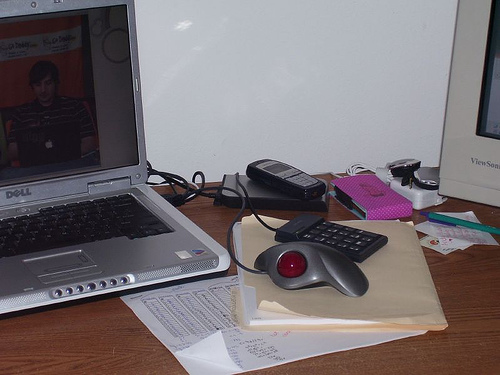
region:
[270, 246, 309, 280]
red roller ball on mouse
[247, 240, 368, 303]
silver computer mouse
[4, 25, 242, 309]
Dell laptop opened up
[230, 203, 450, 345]
manila file folder being used as mouse pad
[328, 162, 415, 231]
hot pink cell phone case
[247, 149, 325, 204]
old black cell phone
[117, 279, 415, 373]
folded paper with scribble on it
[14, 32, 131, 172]
laptop monitor turned off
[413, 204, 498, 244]
aqua and dark blue pen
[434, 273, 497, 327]
grain of wooden desk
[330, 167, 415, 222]
a pink case laying on a desk.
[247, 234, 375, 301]
A large gray mouse with a red ball.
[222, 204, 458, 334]
A file folder with two objects on top of it.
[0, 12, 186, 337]
A Dell laptop sitting open on a desk.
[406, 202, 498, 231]
A turquoise and purple pen.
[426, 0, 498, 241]
A computer monitor.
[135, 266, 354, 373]
Paperwork laying on a desk.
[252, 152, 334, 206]
cell phone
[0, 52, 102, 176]
A picture of a man on a computer screen.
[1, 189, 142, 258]
computer keyboard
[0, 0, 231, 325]
A silver dell laptop.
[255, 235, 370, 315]
A mouse with a red ball in it.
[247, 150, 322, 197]
A cellphone.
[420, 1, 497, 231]
A monitor.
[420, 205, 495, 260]
Papers under a green and purple pen.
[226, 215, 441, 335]
A folder full of papers.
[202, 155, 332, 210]
An external hard drive with a phone on top of it.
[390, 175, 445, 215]
A charger for an apple computer.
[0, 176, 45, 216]
The name of the computer manufacturer.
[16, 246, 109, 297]
The laptop's trackpad.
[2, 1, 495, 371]
a table with many objects on it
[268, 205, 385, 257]
black and white external numeric keypad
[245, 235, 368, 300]
silver and red stationary mouse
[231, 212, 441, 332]
manilla folder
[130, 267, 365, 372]
paper with several columns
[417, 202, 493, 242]
pen resting on papers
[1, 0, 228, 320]
grey laptop computer on table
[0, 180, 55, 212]
brand of laptop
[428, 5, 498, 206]
white computer monitor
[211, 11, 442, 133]
wall is painted white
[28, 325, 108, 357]
shiny dark brown surface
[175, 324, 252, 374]
up turned edge of white paper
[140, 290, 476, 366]
large piece of white paper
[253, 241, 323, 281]
red circular shiny button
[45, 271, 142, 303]
many buttons on silver laptop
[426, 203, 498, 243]
thin blue pen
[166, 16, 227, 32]
small spot on white walls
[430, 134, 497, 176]
edge of silver television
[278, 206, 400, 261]
wide black remote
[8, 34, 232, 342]
silver laptop on table